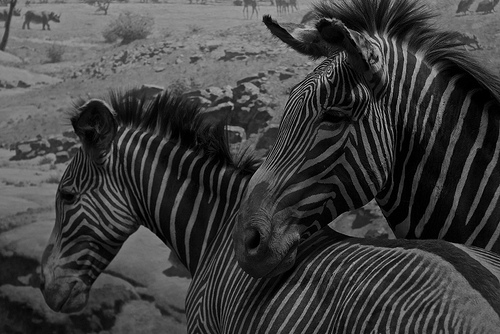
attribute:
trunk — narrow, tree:
[1, 0, 16, 50]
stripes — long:
[146, 136, 267, 303]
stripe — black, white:
[298, 120, 355, 163]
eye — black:
[318, 92, 353, 132]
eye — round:
[314, 108, 344, 124]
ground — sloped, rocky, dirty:
[6, 2, 483, 325]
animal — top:
[4, 5, 57, 34]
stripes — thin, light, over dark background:
[301, 275, 433, 327]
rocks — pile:
[75, 30, 200, 97]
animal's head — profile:
[37, 100, 144, 312]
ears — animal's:
[321, 19, 388, 97]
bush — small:
[95, 2, 192, 52]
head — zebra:
[225, 1, 402, 282]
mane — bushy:
[120, 74, 241, 166]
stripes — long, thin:
[282, 103, 412, 198]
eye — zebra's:
[313, 97, 354, 134]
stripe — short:
[307, 129, 344, 162]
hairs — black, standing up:
[106, 76, 253, 134]